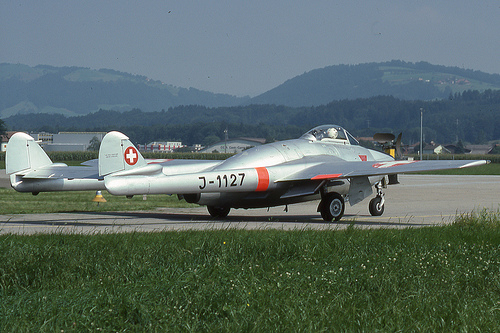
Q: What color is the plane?
A: Silver.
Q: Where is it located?
A: A runway.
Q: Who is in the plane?
A: The pilot.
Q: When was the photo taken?
A: Daylight hours.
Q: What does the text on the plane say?
A: J-1127.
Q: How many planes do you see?
A: One.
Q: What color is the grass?
A: Green.